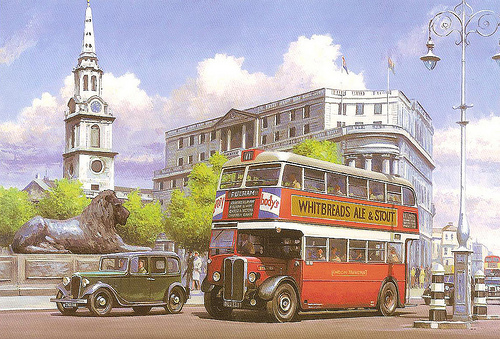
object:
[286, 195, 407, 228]
placard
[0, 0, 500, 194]
sky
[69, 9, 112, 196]
tower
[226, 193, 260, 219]
placard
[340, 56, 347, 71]
flag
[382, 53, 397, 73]
flag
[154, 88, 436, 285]
building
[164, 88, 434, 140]
balcony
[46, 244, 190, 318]
car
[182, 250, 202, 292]
couple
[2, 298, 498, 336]
street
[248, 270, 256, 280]
headlight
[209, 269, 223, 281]
headlight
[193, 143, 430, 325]
bus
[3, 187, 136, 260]
lion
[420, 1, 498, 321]
street lamp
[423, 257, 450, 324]
pylons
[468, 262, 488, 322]
pylons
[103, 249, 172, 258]
roof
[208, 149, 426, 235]
upper level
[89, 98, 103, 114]
clock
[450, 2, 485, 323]
post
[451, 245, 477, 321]
base